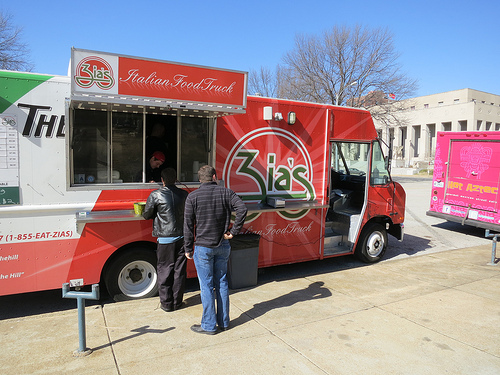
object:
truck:
[0, 47, 405, 304]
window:
[68, 101, 215, 189]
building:
[367, 88, 500, 175]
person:
[184, 165, 248, 335]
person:
[141, 168, 190, 312]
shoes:
[190, 323, 234, 334]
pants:
[192, 239, 229, 332]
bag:
[229, 234, 261, 290]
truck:
[425, 131, 500, 234]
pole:
[59, 283, 99, 358]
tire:
[105, 244, 160, 302]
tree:
[279, 28, 405, 106]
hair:
[198, 165, 218, 183]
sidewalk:
[0, 245, 500, 374]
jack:
[142, 185, 190, 237]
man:
[144, 151, 165, 182]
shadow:
[224, 281, 332, 330]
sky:
[0, 0, 499, 109]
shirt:
[184, 181, 248, 252]